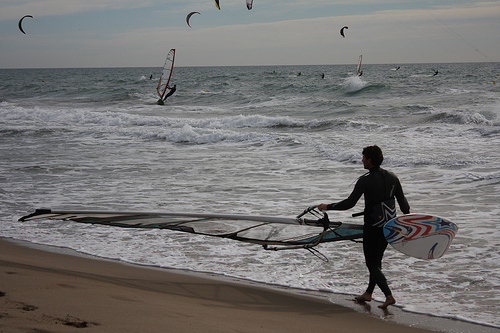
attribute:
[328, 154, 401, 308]
person — walking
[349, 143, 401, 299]
wetsuit — black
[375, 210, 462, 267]
board — red, white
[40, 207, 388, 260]
sail — for surfing, large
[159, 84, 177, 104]
person — windsurfing, sailing, leaning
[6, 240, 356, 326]
beach — sandy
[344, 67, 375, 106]
wave — large, white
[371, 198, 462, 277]
boat — for surfing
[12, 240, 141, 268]
sand — clear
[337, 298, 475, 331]
water — shallow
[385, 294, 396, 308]
heel — raised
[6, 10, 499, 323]
image — beach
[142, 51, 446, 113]
people — kitesurfing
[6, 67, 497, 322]
ocean — choppy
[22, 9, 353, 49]
kites — curved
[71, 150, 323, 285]
surf — white